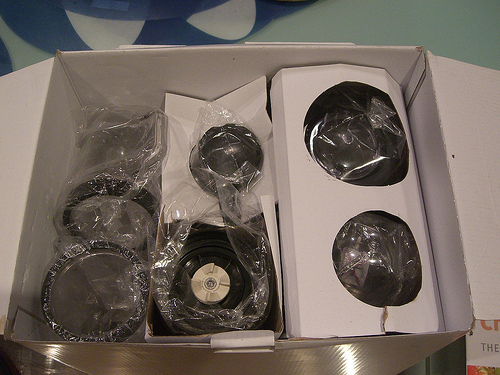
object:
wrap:
[61, 105, 181, 235]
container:
[52, 170, 170, 251]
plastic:
[149, 196, 278, 337]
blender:
[141, 221, 282, 344]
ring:
[149, 226, 271, 336]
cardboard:
[154, 74, 277, 226]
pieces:
[184, 112, 274, 195]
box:
[1, 36, 499, 373]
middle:
[136, 63, 290, 346]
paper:
[286, 196, 309, 325]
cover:
[261, 58, 448, 346]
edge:
[45, 35, 433, 56]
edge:
[61, 234, 141, 250]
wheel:
[32, 236, 150, 341]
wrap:
[299, 76, 416, 193]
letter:
[478, 341, 488, 352]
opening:
[295, 77, 415, 189]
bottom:
[327, 208, 431, 315]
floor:
[320, 9, 498, 37]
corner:
[395, 41, 440, 110]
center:
[201, 275, 221, 291]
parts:
[305, 101, 392, 184]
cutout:
[183, 118, 274, 204]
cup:
[36, 233, 158, 350]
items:
[185, 115, 272, 203]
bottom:
[187, 260, 235, 307]